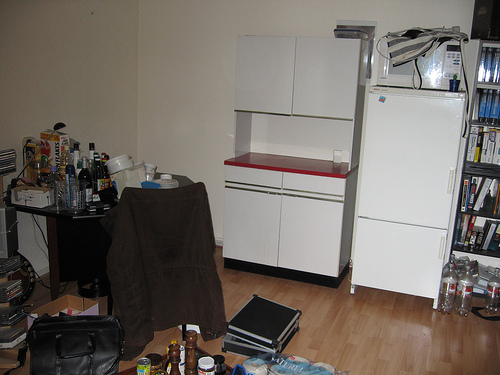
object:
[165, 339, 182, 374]
mill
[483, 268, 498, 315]
bottle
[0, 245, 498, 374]
floor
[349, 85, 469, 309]
fridge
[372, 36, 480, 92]
microwave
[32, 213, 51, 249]
cords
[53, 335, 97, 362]
handle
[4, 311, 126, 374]
bag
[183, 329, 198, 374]
pepper mill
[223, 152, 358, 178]
shelf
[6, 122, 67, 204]
desktop lamp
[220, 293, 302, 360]
case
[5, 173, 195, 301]
table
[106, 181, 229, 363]
jacket